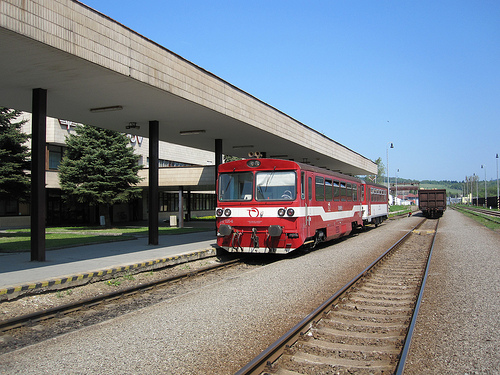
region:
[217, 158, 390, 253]
A red train with many windows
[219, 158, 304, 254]
The front of a red train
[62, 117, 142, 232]
Pine tree in front of a building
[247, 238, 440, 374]
A set of train tracks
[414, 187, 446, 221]
A brown train cart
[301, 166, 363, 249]
The side of a red train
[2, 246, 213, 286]
Caution tape by train tracks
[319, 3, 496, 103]
A clear blue sky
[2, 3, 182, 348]
An over hang next to train tracks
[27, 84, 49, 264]
A post holding up an overhang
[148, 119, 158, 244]
Brown pillar supporting cover.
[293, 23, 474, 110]
Blue cloudless sky.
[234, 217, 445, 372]
Railroad tracks with rock ground cover.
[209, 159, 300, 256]
Front of red train at station.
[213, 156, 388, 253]
Red and white train at station.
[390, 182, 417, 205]
Red roofed buildings in background.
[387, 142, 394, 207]
Tall light pole lining station.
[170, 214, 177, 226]
White trash bin at station.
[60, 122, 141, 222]
Tall evergreen tree near building.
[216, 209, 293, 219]
Lights on front of train.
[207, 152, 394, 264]
red and white train on train station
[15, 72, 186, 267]
black steal beams holding white ceiling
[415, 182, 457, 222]
black train cart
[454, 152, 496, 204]
lots of street lights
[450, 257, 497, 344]
grown filled with gravel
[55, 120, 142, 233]
green pine tree on front of building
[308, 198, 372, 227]
white broken stripe line on side of train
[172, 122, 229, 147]
rectangle ceiling lights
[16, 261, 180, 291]
black and yellow painted stripes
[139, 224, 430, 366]
two trains tracks leading at opposite directions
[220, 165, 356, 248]
this is a train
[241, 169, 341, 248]
the train is red in color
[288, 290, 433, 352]
this is the rail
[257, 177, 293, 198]
this is the front screen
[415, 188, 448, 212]
this is a carriage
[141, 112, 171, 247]
this is a pole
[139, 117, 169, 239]
the pole is straight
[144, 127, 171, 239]
the pole is wooden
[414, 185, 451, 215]
the carriage is metallic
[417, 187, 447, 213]
the carriage is rusty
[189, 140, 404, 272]
train sitting on tracks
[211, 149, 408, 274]
train is red and white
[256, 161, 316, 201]
white shade in train windshield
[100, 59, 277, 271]
passenger walkway along tracks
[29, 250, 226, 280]
yellow and black markings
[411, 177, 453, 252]
train car on train tracks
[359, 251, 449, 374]
silver rail of train track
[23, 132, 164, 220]
green tree near building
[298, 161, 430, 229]
windows on train cars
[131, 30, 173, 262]
post from ceiling to sidewalk